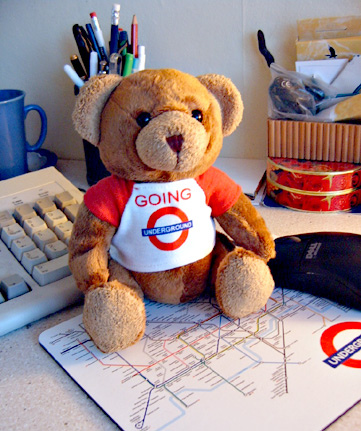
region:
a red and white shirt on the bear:
[80, 167, 249, 282]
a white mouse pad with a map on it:
[33, 278, 358, 427]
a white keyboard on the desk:
[1, 176, 125, 348]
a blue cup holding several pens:
[76, 3, 151, 187]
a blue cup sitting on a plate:
[0, 81, 62, 195]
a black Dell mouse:
[235, 217, 360, 315]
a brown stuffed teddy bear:
[53, 68, 280, 360]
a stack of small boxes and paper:
[259, 15, 360, 161]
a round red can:
[258, 152, 360, 214]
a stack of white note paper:
[181, 144, 274, 206]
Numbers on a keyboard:
[2, 176, 88, 299]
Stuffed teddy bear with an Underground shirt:
[79, 64, 273, 342]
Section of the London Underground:
[164, 316, 357, 406]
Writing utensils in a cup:
[68, 7, 145, 76]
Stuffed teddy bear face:
[88, 74, 234, 174]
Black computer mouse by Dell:
[271, 220, 359, 290]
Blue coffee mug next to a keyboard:
[0, 86, 54, 174]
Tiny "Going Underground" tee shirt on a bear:
[97, 173, 243, 267]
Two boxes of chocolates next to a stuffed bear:
[264, 146, 359, 219]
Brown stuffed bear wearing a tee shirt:
[70, 68, 272, 347]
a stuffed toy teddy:
[100, 235, 272, 415]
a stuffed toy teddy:
[144, 225, 199, 416]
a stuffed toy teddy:
[92, 207, 217, 375]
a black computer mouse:
[261, 226, 360, 310]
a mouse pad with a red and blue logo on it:
[52, 255, 356, 428]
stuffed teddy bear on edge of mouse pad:
[59, 62, 276, 359]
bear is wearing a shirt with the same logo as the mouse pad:
[86, 129, 359, 373]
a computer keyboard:
[0, 162, 103, 334]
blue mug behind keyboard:
[0, 76, 55, 233]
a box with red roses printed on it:
[262, 153, 359, 213]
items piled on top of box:
[249, 10, 359, 198]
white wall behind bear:
[150, 11, 259, 163]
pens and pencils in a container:
[75, 1, 152, 189]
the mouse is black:
[265, 217, 359, 310]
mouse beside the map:
[254, 216, 359, 402]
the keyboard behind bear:
[16, 95, 254, 324]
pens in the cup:
[59, 27, 149, 183]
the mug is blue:
[3, 91, 54, 172]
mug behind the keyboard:
[2, 92, 86, 301]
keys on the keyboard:
[2, 200, 82, 284]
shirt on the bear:
[71, 77, 278, 340]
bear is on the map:
[80, 98, 300, 384]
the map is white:
[57, 327, 334, 429]